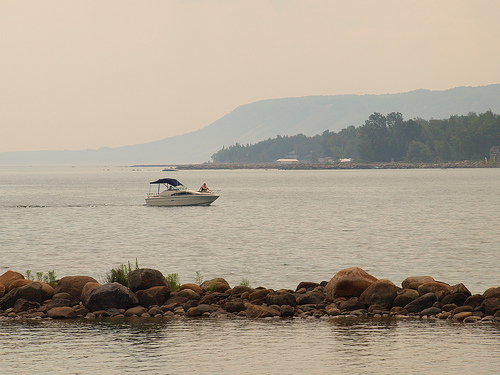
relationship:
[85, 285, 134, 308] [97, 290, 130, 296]
rock has parts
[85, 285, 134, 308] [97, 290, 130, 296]
rock has edge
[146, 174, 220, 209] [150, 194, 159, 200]
boat has parts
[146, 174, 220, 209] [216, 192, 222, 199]
boat has a tip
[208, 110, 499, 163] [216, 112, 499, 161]
forest has an edge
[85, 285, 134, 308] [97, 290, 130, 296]
rock has an edge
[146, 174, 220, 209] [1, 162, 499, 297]
boat in bay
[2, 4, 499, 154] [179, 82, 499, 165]
sky above mountains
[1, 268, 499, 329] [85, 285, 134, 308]
jetty made of rock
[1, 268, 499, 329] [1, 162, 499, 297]
jetty in bay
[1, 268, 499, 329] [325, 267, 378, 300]
jetty made of rock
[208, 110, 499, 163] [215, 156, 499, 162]
forest on land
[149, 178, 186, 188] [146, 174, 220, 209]
canvas on boat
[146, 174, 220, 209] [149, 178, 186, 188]
boat has canvas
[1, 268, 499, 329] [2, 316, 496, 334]
rocks have reflection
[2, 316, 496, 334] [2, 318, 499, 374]
reflection in water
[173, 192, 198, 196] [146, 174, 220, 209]
windows on boat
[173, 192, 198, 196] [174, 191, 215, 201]
windows are on cabin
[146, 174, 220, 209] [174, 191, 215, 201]
boat has a cabin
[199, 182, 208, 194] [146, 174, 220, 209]
person on boat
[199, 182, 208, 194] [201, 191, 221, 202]
person in front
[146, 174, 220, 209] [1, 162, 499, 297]
boat in water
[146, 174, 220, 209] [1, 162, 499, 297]
boat on water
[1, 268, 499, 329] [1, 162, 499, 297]
rocks are in water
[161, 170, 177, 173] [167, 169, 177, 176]
island in middle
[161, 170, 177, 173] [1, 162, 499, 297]
island in water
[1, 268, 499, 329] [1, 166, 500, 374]
rocks are in water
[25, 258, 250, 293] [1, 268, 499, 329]
grass in rocks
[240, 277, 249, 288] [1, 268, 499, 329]
grass in rocks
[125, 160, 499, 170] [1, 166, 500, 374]
land by water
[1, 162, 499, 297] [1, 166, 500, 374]
ocean made out of water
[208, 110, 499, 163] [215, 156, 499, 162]
trees are on land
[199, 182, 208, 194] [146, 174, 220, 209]
man on boat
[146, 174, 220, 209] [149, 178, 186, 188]
boat has a canopy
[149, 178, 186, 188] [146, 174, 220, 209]
canopy on top of boat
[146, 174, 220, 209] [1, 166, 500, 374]
boat on water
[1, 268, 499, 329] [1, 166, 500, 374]
rocks in water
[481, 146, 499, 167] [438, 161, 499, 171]
home on shore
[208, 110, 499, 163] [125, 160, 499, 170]
trees are on land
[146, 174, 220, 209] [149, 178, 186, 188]
boat has a top